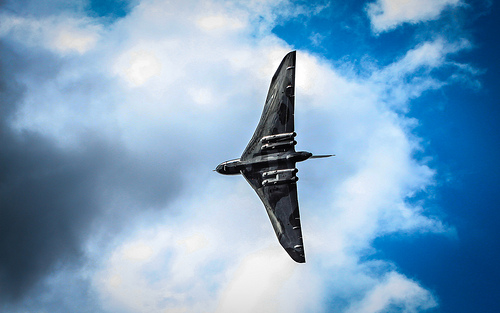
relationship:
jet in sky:
[212, 50, 335, 263] [0, 2, 499, 312]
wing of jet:
[240, 50, 301, 160] [212, 50, 335, 263]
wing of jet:
[240, 164, 306, 264] [212, 50, 335, 263]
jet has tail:
[212, 50, 335, 263] [309, 153, 336, 160]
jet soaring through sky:
[212, 50, 335, 263] [0, 2, 499, 312]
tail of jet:
[309, 153, 336, 160] [212, 50, 335, 263]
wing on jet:
[240, 50, 301, 160] [212, 50, 335, 263]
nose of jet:
[213, 157, 244, 175] [212, 50, 335, 263]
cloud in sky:
[12, 1, 441, 312] [0, 2, 499, 312]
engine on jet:
[262, 133, 298, 152] [212, 50, 335, 263]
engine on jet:
[262, 167, 300, 187] [212, 50, 335, 263]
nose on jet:
[213, 157, 244, 175] [212, 50, 335, 263]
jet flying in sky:
[212, 50, 335, 263] [0, 2, 499, 312]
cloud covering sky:
[12, 1, 441, 312] [0, 2, 499, 312]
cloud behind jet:
[12, 1, 441, 312] [212, 50, 335, 263]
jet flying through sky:
[212, 50, 335, 263] [0, 2, 499, 312]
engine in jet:
[262, 167, 300, 187] [212, 50, 335, 263]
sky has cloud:
[0, 2, 499, 312] [12, 1, 441, 312]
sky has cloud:
[0, 2, 499, 312] [0, 25, 183, 313]